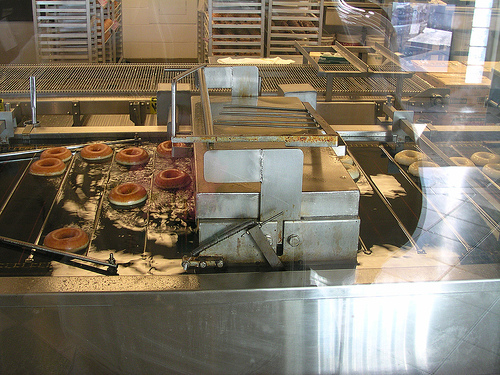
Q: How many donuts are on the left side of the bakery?
A: Eight.